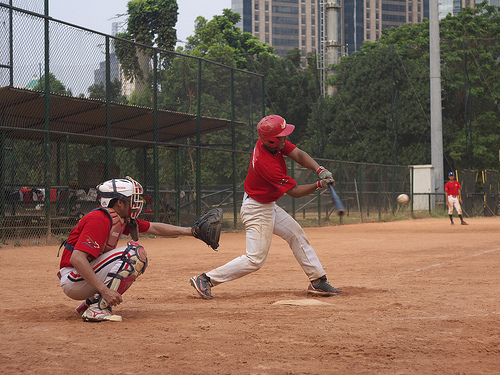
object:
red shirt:
[243, 139, 297, 204]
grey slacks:
[205, 191, 328, 288]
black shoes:
[306, 274, 344, 297]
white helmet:
[95, 174, 145, 220]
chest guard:
[115, 240, 149, 297]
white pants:
[55, 245, 149, 309]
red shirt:
[58, 206, 151, 270]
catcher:
[55, 174, 224, 323]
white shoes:
[81, 302, 123, 323]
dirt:
[349, 221, 469, 362]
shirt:
[444, 180, 462, 197]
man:
[444, 171, 469, 225]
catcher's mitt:
[190, 207, 224, 252]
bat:
[327, 183, 346, 218]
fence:
[0, 0, 415, 250]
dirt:
[0, 250, 49, 362]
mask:
[125, 175, 145, 220]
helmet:
[256, 114, 296, 149]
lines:
[394, 246, 500, 278]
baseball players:
[189, 114, 349, 300]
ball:
[397, 193, 411, 204]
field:
[0, 212, 499, 375]